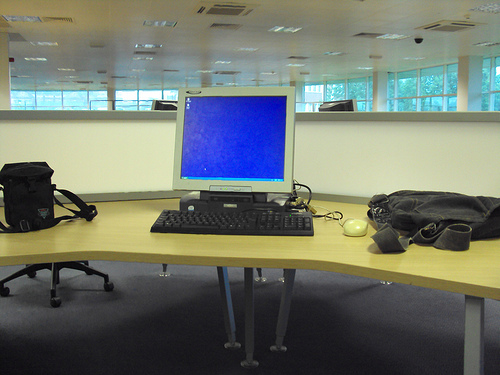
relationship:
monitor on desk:
[172, 86, 296, 194] [0, 194, 500, 374]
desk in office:
[0, 194, 500, 374] [5, 5, 498, 374]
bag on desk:
[0, 158, 98, 235] [0, 196, 499, 296]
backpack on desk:
[367, 189, 500, 254] [0, 176, 497, 373]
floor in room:
[1, 266, 498, 372] [1, 0, 498, 370]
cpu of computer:
[182, 181, 268, 222] [147, 83, 316, 239]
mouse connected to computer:
[342, 202, 372, 257] [147, 83, 316, 239]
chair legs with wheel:
[2, 260, 116, 308] [25, 270, 38, 280]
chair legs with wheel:
[2, 260, 116, 308] [0, 284, 12, 298]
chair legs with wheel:
[2, 260, 116, 308] [48, 295, 63, 307]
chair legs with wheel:
[2, 260, 116, 308] [102, 280, 115, 292]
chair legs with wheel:
[2, 260, 116, 308] [83, 267, 95, 275]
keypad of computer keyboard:
[282, 214, 310, 231] [150, 208, 315, 236]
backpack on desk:
[367, 189, 500, 254] [0, 196, 499, 296]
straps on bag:
[368, 218, 474, 254] [366, 188, 498, 241]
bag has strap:
[0, 158, 98, 235] [0, 185, 97, 232]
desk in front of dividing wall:
[0, 176, 497, 373] [1, 107, 498, 209]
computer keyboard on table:
[148, 205, 316, 239] [1, 196, 498, 373]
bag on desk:
[0, 158, 98, 235] [0, 194, 500, 374]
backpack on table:
[336, 172, 484, 266] [341, 232, 481, 294]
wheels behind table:
[0, 268, 115, 308] [1, 196, 498, 373]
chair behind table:
[3, 257, 114, 307] [1, 196, 498, 373]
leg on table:
[271, 270, 296, 352] [1, 196, 498, 373]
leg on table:
[238, 265, 259, 367] [1, 196, 498, 373]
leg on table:
[216, 266, 241, 348] [1, 196, 498, 373]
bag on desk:
[0, 161, 98, 234] [2, 182, 498, 301]